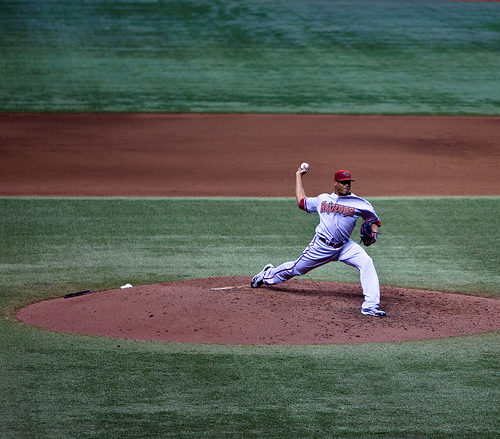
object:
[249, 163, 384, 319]
baseball player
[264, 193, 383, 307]
uniform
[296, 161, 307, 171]
hand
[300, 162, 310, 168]
ball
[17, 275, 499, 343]
mound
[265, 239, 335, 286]
leg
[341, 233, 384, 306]
leg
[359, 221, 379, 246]
hand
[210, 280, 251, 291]
line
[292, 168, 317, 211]
arm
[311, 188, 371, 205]
back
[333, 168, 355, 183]
cap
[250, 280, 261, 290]
toe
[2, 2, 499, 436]
grass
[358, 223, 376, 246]
glove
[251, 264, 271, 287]
cleat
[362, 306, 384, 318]
cleat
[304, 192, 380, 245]
shirt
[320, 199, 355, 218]
letters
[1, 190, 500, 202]
line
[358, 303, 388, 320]
foot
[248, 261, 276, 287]
foot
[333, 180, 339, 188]
ear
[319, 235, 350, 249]
belt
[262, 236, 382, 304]
pants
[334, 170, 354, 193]
head